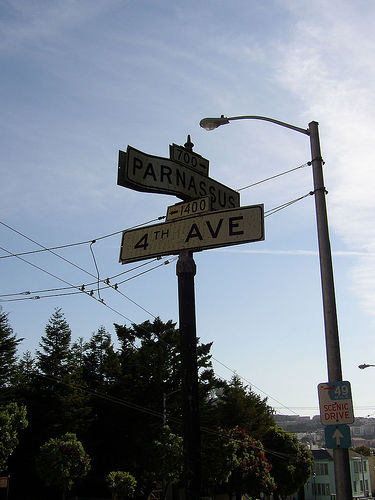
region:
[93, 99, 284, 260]
group of street signs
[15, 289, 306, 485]
bunch of green leafy trees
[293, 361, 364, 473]
small street sign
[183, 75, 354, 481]
tall grey street light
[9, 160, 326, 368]
telephone wires high in the air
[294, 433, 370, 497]
small building with windows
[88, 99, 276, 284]
rectangular white street signs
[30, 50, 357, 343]
blue sky with wispy clouds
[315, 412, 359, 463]
blue sign with white arrow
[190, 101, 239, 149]
large light at the end of a pole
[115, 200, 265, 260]
black and white 4th AVE street sign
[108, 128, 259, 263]
black and white street signs on a pole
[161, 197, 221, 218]
black and white street sign reading 1400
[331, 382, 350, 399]
the number 49 printed on a sign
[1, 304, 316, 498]
group of trees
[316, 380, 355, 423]
sign reading 49 scenic drive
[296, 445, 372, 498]
very tall building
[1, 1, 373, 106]
white clouds in a blue sky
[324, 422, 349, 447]
white arrow on a sign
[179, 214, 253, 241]
black text reading AVE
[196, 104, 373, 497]
a silver street light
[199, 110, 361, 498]
sign attached to street light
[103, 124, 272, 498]
a street sign pole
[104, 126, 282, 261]
a white sign with black writing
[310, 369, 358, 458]
signs are blue, white and red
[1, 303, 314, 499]
a group of trees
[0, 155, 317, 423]
wires cross over the road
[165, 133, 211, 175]
sign with the numbers 7 0 0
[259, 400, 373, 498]
buildings behind street light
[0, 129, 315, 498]
trees behind street sign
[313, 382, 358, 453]
white red and blue street sign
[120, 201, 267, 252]
white and black street name sign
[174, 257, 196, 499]
black metal street sign pole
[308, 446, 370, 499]
white and black house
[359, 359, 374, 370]
silver metal street lamp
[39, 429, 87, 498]
tree with green leaves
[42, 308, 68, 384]
green evergreen tree by road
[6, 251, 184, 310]
black electrical wired to pole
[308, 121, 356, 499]
grey metal light pole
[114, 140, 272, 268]
intersection street signs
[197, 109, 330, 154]
A street lamp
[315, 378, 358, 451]
A sign pointing the way to scenic drive number 49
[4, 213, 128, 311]
Overhead electrical wires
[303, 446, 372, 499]
A tall white house with a black roof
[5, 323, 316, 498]
Trees along the left side of the street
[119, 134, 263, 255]
A sign at the intersection of 4th Ave and Parnassus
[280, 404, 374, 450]
A city skyline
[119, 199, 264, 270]
Street sign indicating that the 1400 block of 4th Ave is to the left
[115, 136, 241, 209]
Street sign pointing to the 700 block of Parnassus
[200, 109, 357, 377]
A tall grey metal pole holding up a street light